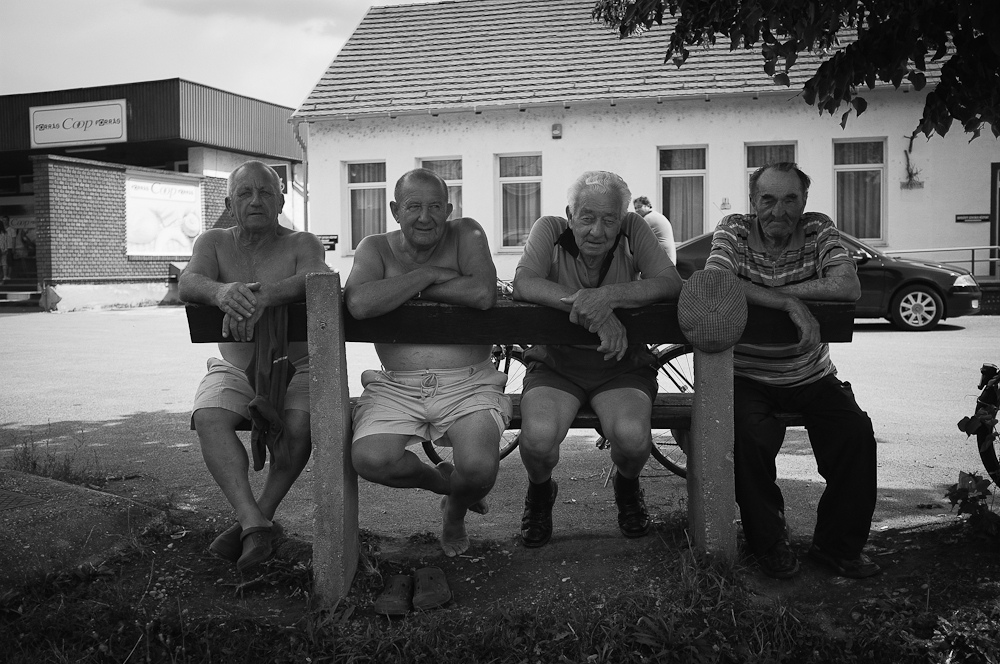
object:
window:
[340, 159, 386, 257]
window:
[414, 153, 463, 222]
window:
[489, 150, 541, 253]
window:
[655, 144, 706, 248]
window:
[743, 140, 798, 214]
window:
[832, 137, 889, 251]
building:
[288, 0, 999, 279]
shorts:
[191, 354, 319, 430]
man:
[177, 160, 323, 571]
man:
[343, 168, 511, 559]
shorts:
[352, 354, 515, 449]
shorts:
[517, 342, 659, 414]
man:
[512, 170, 684, 549]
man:
[702, 160, 885, 577]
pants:
[734, 375, 877, 553]